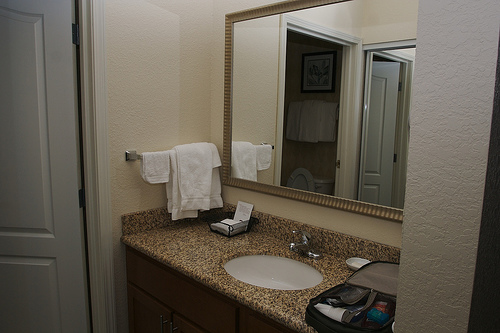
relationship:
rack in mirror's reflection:
[284, 97, 339, 112] [232, 20, 412, 205]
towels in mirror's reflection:
[286, 100, 298, 142] [232, 20, 412, 205]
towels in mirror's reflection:
[286, 100, 337, 143] [232, 20, 412, 205]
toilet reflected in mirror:
[286, 167, 333, 195] [230, 0, 417, 210]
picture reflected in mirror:
[299, 48, 339, 94] [226, 19, 438, 194]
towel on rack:
[140, 142, 223, 220] [125, 147, 142, 161]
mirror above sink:
[230, 0, 417, 210] [216, 225, 331, 294]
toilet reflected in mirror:
[286, 167, 333, 191] [280, 27, 415, 212]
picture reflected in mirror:
[299, 48, 339, 94] [230, 0, 417, 210]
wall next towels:
[95, 25, 229, 137] [112, 123, 242, 240]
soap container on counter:
[346, 257, 372, 271] [114, 197, 386, 332]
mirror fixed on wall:
[230, 0, 417, 210] [181, 9, 406, 251]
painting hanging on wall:
[293, 48, 340, 99] [280, 38, 340, 196]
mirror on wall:
[230, 0, 417, 210] [110, 27, 197, 132]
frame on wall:
[205, 5, 320, 13] [110, 27, 197, 132]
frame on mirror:
[205, 5, 320, 13] [230, 0, 417, 210]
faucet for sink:
[286, 227, 323, 257] [224, 242, 326, 290]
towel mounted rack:
[125, 127, 223, 210] [117, 148, 140, 165]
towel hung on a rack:
[140, 142, 223, 220] [124, 147, 137, 164]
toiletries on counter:
[321, 272, 386, 330] [114, 197, 386, 332]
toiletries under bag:
[321, 272, 386, 330] [303, 257, 398, 331]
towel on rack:
[140, 142, 223, 220] [112, 139, 142, 173]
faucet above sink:
[288, 231, 323, 260] [217, 250, 327, 293]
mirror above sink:
[230, 0, 417, 210] [209, 233, 329, 295]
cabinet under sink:
[122, 244, 312, 331] [217, 247, 328, 291]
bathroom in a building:
[0, 0, 500, 330] [21, 8, 471, 329]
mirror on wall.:
[230, 0, 417, 210] [103, 30, 200, 115]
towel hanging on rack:
[140, 142, 223, 220] [117, 138, 228, 178]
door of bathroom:
[0, 8, 82, 331] [0, 0, 500, 330]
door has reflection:
[358, 41, 418, 208] [236, 0, 420, 203]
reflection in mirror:
[236, 0, 420, 203] [219, 0, 421, 221]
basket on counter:
[207, 203, 259, 235] [170, 236, 229, 266]